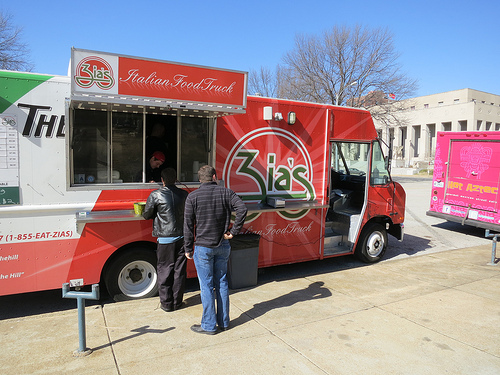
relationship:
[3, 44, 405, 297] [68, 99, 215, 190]
truck has window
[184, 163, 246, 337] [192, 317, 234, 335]
person wearing shoes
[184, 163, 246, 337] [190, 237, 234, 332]
person wearing pants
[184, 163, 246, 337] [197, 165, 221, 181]
person has hair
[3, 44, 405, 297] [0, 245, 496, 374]
truck beside sidewalk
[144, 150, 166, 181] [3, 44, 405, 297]
man in truck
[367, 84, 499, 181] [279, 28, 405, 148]
building near tree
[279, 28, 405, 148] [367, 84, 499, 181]
tree near building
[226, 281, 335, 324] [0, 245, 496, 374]
shadow on sidewalk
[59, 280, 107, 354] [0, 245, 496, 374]
pole in sidewalk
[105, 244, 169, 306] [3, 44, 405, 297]
tire on truck